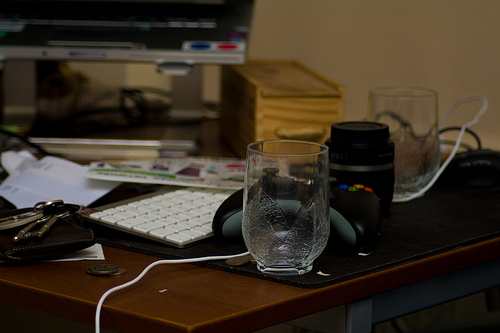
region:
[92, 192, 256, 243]
The keyboard on the table.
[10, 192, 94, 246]
The keys on the table.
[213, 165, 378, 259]
The game controller on the table.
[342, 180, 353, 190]
The blue button on the game controller.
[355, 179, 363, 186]
The yellow button on the game controller.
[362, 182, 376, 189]
The red button on the game controller.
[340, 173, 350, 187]
The blue button on the game controller.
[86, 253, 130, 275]
The coins on the table.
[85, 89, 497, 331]
The white wire on the table.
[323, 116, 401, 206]
The black camera lens on the table.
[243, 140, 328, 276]
the clear glass on the desk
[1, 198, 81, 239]
the keys on the desk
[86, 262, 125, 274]
the coins on the desk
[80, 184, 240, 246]
the apple keyboard on the desk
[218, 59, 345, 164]
the small wood box on the desk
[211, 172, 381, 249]
the xbox controller on the desk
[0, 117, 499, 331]
the dark brown desk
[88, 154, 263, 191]
the paper partially on the keyboard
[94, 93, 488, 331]
the white wire on the desk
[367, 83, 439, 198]
the clear glass next to the wooden box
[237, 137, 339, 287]
the glass is empty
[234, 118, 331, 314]
the glass is empty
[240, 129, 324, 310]
the glass is empty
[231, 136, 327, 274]
the glass is empty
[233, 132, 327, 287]
the glass is empty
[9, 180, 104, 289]
keys and wallet on the table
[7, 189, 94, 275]
keys and wallet on the table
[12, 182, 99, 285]
keys and wallet on the table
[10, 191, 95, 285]
keys and wallet on the table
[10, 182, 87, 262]
keys and wallet on the table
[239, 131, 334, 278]
a glass of water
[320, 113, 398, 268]
a can of deoderant spray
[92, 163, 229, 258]
a flat white keyboard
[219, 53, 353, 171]
a wooden storage box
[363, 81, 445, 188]
an empty water glass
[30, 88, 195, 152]
a small digital dvd player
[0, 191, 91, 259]
some keys and a keyholder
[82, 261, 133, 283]
pennies in a stack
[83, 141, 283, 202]
a cd on its side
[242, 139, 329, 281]
Empty glass on the desk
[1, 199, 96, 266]
Keys on top of a wallet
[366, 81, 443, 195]
Empty glass on the desk